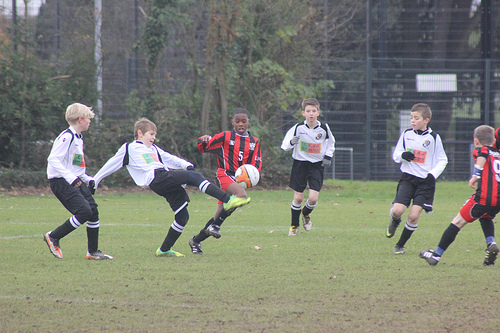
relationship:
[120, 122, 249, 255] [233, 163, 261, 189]
kid playing soccer ball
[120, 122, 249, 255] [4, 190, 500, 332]
kid on field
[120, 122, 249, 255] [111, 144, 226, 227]
kid wearing uniform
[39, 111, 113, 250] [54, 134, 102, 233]
kid wearing uniform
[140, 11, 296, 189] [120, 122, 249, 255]
tree behind kid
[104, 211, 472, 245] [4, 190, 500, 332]
line on field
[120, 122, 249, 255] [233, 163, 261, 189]
kid kicking soccer ball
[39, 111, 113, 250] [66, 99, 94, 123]
kid has hair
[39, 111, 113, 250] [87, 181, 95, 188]
kid wearing glove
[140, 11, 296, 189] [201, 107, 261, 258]
tree behind kid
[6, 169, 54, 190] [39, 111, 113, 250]
hedges behind kid